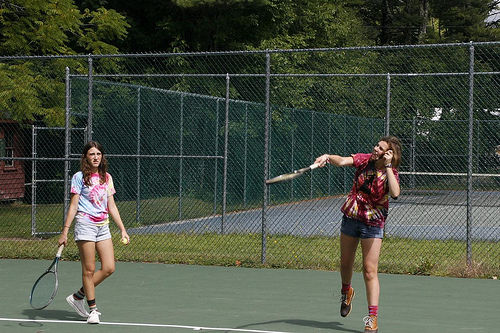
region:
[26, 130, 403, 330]
Two women are on a tennis court.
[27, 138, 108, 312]
A woman is holding a tennis racket.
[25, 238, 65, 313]
The colors of a tennis racket are white, blue, and gray.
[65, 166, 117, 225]
The colors of a shirt are blue-white, and pink.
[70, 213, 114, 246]
A woman is wearing white shorts.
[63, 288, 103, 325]
A woman is wearing white and black shoes.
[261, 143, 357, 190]
A woman is swinging a tennis racket.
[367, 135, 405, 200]
A woman is talking on a cell phone.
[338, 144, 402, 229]
A woman is wearing a red, black, and yellow top.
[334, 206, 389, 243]
A woman is wearing blue shorts.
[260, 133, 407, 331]
young lady serves the ball while talking on the phone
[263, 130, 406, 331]
young woman does not seem especially focused on her game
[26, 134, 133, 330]
phone lady's doubles partner does not look thrilled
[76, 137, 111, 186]
phone lady's doubles partner has long curly hair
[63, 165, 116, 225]
phone lady's doubles partner wearing a pink and blue tie-dyed shirt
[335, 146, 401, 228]
phone lady wearing a maroon tie-dyed shirt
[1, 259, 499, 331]
tennis court is a green hard court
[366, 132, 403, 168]
phone lady looks quite happy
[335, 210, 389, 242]
phone lady wearing blue shorts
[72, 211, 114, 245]
phone lady's doubles partner wearing light colored shorts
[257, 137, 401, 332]
a woman wearing red playing tennis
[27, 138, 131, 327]
a woman wearing red playing tennis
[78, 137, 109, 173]
the head of woman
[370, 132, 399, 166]
the head of woman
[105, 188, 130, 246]
the arm of a woman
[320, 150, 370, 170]
the arm of a woman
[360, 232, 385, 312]
the leg of a woman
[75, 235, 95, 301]
the leg of a woman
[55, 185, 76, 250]
the arm of a woman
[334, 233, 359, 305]
the leg of a woman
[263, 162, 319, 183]
A tennis racket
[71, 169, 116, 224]
A colorful t-shirt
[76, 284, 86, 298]
A black sock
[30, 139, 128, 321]
A female with a tennis racket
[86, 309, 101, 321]
A white shoe with white shoelace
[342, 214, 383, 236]
A pair of blue short pants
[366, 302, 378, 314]
A red sock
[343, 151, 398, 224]
A red t-shirt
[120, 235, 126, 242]
A tennis ball in a hand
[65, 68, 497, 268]
A green fence in the background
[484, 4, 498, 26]
blue of daytime sky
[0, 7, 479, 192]
green leaves on trees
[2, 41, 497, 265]
poles on chain link fence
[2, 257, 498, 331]
green surface of tennis court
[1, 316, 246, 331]
white line on court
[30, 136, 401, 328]
two girls on tennis court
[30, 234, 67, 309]
hand holding tennis racket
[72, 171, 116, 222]
tie dye tee shirt on girl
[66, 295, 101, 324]
white shoes on girl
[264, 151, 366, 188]
arm swinging tennis racket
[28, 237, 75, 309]
A girl is holding a tennis racket.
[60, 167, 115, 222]
A girl is wearing a tye dye shirt.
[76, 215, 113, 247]
A girl is wearing jean shorts.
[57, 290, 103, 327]
A girl is wearing white shoes.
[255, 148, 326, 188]
A girl is holding a tennis racket.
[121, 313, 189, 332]
A white line is painted on the tennis court.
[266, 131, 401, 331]
the girl swinging the racket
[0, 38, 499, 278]
the chain link fence is tall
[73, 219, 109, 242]
the shorts are light blue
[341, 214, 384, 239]
the shorts are dark blue